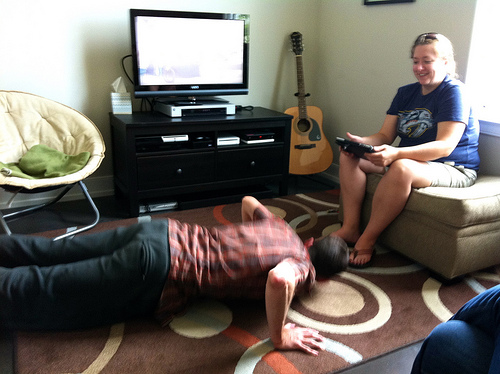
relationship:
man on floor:
[7, 189, 347, 351] [3, 182, 492, 373]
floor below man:
[3, 182, 492, 373] [7, 189, 347, 351]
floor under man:
[3, 182, 492, 373] [7, 189, 347, 351]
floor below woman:
[3, 182, 492, 373] [337, 19, 475, 270]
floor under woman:
[3, 182, 492, 373] [337, 19, 475, 270]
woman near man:
[337, 19, 475, 270] [7, 189, 347, 351]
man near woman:
[7, 189, 347, 351] [337, 19, 475, 270]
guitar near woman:
[285, 25, 336, 175] [337, 19, 475, 270]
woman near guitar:
[337, 19, 475, 270] [285, 25, 336, 175]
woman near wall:
[337, 19, 475, 270] [1, 1, 492, 167]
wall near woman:
[1, 1, 492, 167] [337, 19, 475, 270]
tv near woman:
[120, 4, 258, 104] [337, 19, 475, 270]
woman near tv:
[337, 19, 475, 270] [120, 4, 258, 104]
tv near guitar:
[120, 4, 258, 104] [285, 25, 336, 175]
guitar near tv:
[285, 25, 336, 175] [120, 4, 258, 104]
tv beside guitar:
[120, 4, 258, 104] [285, 25, 336, 175]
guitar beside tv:
[285, 25, 336, 175] [120, 4, 258, 104]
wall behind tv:
[1, 1, 492, 167] [120, 4, 258, 104]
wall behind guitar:
[1, 1, 492, 167] [285, 25, 336, 175]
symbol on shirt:
[399, 108, 433, 138] [384, 80, 478, 167]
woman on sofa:
[312, 32, 479, 269] [415, 186, 493, 269]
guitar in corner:
[281, 31, 333, 175] [304, 42, 324, 58]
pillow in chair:
[17, 144, 84, 176] [0, 88, 103, 244]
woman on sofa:
[312, 32, 479, 269] [335, 162, 498, 279]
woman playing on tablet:
[312, 32, 479, 269] [333, 131, 376, 156]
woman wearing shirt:
[312, 32, 479, 269] [388, 80, 488, 167]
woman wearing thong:
[312, 32, 479, 269] [353, 255, 358, 256]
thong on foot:
[353, 255, 358, 256] [346, 246, 378, 266]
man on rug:
[1, 189, 347, 356] [335, 279, 438, 326]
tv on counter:
[120, 4, 254, 118] [110, 108, 293, 126]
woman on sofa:
[337, 19, 475, 270] [335, 162, 498, 279]